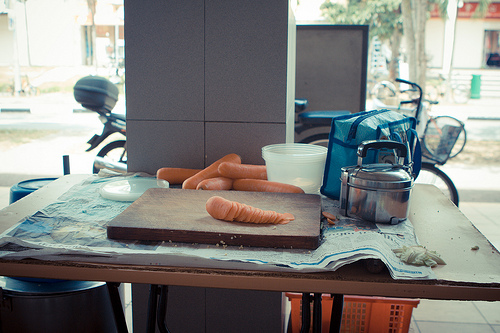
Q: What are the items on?
A: A large table.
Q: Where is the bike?
A: Next to the table.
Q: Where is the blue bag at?
A: On the table.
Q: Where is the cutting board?
A: On the table.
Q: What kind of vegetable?
A: Carrots.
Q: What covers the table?
A: Newspaper.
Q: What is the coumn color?
A: Grey.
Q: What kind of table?
A: Wooden.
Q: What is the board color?
A: Brown.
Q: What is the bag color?
A: Blue.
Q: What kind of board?
A: Cutting.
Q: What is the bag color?
A: Blue.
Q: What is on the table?
A: Cutting board.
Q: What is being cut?
A: Carrots.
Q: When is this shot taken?
A: Daytime.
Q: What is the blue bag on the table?
A: Lunch pail.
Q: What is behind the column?
A: Bike.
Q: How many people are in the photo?
A: 0.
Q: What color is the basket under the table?
A: Orange.